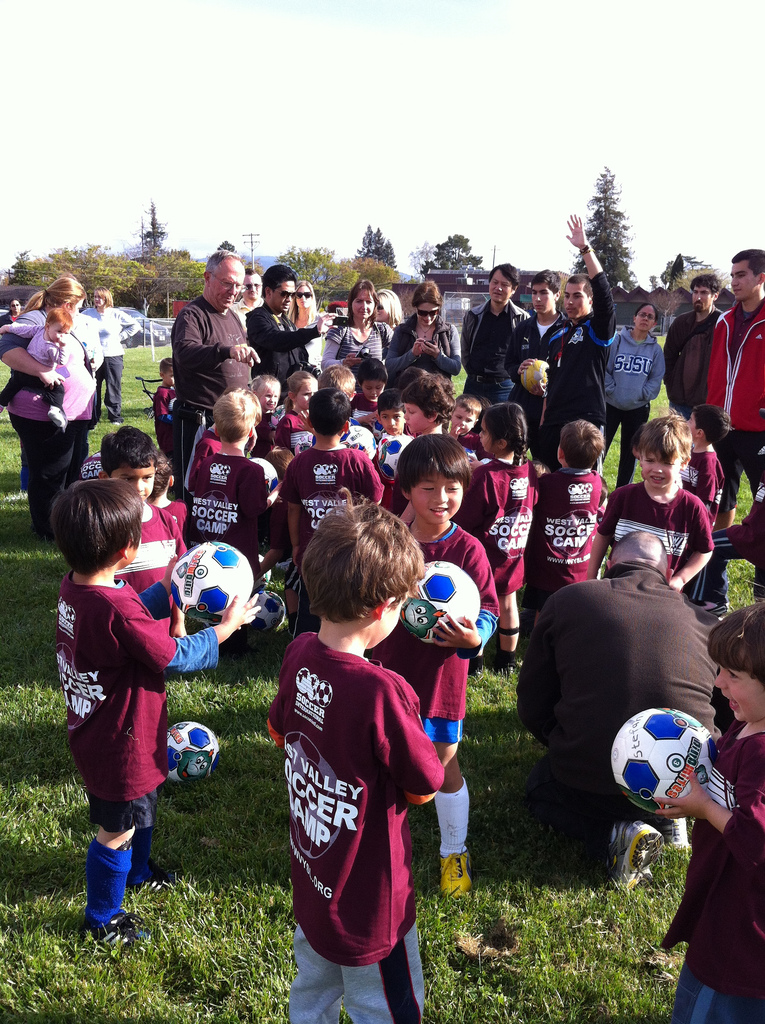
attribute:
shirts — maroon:
[270, 630, 449, 935]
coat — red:
[708, 296, 763, 440]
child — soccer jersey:
[273, 492, 448, 1020]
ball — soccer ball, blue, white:
[610, 703, 714, 808]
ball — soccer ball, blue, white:
[397, 557, 481, 637]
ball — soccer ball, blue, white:
[167, 539, 254, 621]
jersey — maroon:
[264, 625, 447, 967]